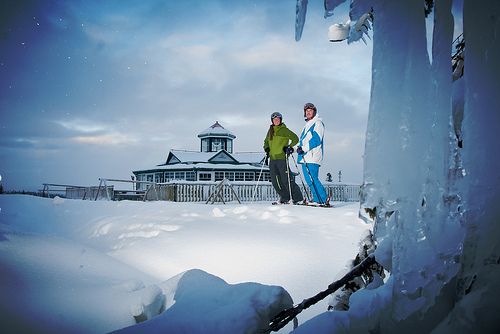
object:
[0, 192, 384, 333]
snow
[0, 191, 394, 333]
ground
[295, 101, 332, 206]
man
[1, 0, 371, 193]
cloudy sky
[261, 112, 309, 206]
person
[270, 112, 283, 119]
snow goggles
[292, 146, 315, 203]
ski pole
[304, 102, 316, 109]
snow goggles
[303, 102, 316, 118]
hair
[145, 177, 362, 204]
wooden fence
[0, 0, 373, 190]
clouds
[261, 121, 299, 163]
coat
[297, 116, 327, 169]
coat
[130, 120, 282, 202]
house